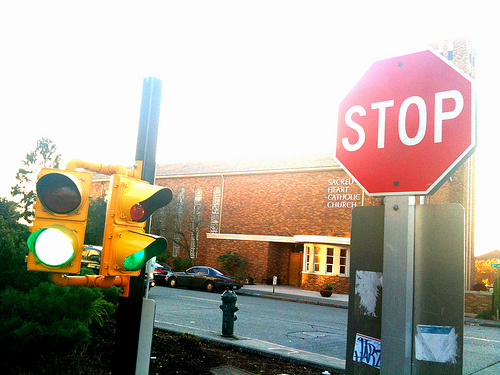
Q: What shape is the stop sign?
A: Octagon.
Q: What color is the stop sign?
A: Red.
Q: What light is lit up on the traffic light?
A: Green.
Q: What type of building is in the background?
A: Church.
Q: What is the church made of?
A: Brick.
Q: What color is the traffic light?
A: Yellow.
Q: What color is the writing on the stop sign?
A: White.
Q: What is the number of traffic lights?
A: 2.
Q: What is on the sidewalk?
A: Fire hydrant.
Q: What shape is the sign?
A: Octagon.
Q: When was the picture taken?
A: Daytime.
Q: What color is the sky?
A: White.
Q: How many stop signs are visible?
A: One.